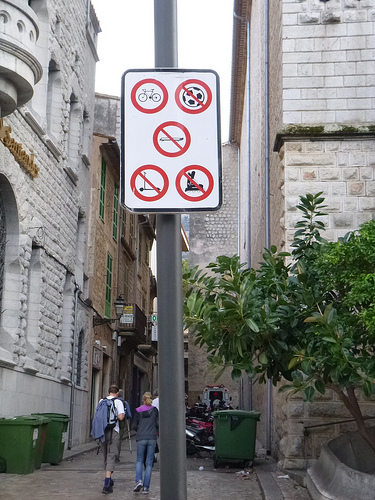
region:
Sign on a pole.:
[97, 63, 233, 228]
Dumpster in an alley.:
[205, 394, 277, 472]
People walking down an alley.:
[71, 367, 176, 474]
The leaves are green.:
[211, 255, 370, 379]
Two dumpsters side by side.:
[6, 401, 81, 464]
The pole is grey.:
[141, 287, 195, 497]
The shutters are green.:
[94, 165, 126, 318]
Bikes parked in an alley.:
[185, 385, 213, 467]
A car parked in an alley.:
[193, 375, 238, 407]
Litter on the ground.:
[194, 463, 297, 485]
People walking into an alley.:
[65, 360, 179, 496]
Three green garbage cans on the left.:
[1, 407, 77, 477]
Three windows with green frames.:
[95, 161, 121, 324]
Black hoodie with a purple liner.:
[132, 395, 166, 448]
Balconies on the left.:
[105, 281, 167, 367]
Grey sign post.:
[138, 11, 200, 492]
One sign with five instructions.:
[102, 50, 234, 221]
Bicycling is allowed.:
[128, 66, 170, 122]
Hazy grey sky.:
[70, 2, 242, 144]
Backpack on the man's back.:
[85, 387, 130, 447]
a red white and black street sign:
[105, 62, 232, 214]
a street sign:
[111, 54, 262, 248]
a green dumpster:
[183, 391, 274, 490]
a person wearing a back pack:
[61, 365, 144, 483]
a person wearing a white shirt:
[87, 379, 138, 496]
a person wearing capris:
[92, 374, 127, 498]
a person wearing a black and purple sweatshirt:
[123, 369, 168, 498]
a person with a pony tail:
[127, 384, 170, 499]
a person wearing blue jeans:
[126, 382, 171, 492]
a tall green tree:
[169, 177, 374, 490]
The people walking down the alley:
[90, 382, 159, 497]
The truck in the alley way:
[194, 382, 231, 413]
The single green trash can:
[206, 403, 265, 473]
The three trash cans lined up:
[0, 410, 73, 476]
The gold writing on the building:
[0, 135, 45, 184]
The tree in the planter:
[181, 184, 374, 464]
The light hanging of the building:
[93, 294, 128, 336]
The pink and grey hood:
[135, 405, 153, 419]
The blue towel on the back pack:
[87, 397, 111, 444]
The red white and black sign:
[113, 57, 238, 221]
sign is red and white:
[110, 64, 234, 223]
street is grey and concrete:
[24, 428, 238, 494]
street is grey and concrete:
[62, 444, 170, 493]